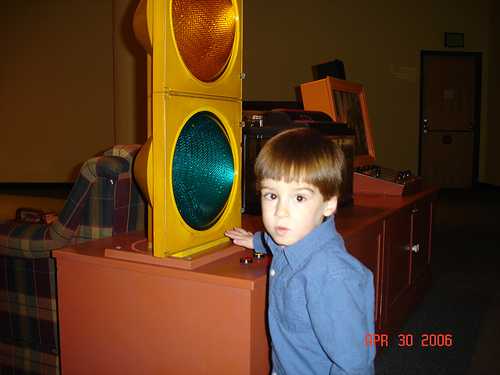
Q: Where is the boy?
A: In front of street light.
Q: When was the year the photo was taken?
A: 2006.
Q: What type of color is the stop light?
A: Yellow.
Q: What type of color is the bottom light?
A: Green.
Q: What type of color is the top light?
A: Yellow.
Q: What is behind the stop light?
A: Chair.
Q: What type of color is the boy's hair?
A: Brown.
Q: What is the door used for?
A: Enter or leave the room.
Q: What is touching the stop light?
A: A boy.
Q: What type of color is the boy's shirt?
A: Blue.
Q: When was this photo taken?
A: Apr 30 2006.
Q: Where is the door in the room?
A: In the back on the right.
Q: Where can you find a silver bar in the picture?
A: On the door.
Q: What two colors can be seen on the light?
A: Green and yellow.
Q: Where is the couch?
A: Behind the cabinet with the stoplight.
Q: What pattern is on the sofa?
A: Plaid.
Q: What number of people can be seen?
A: 1.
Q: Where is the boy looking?
A: At the camera.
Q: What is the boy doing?
A: Pushing a button, looking at the camera.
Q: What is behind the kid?
A: A door.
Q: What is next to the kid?
A: Traffic lights.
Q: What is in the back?
A: A plaid couch.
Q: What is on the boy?
A: A shirt.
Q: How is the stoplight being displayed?
A: On a table.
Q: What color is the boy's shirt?
A: Blue.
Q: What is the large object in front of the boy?
A: A stoplight.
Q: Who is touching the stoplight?
A: The boy.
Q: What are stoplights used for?
A: To keep traffic moving safely.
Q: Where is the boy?
A: In a house.